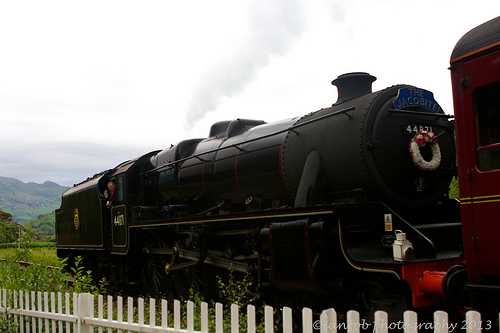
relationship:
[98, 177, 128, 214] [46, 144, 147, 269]
man inside cabin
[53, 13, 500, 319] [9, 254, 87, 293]
train on tracks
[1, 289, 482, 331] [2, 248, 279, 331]
fence on grass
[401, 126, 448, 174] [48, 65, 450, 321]
wreath on train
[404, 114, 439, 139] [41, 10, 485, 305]
numbers on train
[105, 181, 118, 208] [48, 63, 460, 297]
man on train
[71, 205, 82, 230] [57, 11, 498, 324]
sign on train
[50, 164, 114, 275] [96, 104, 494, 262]
back attached to wagon